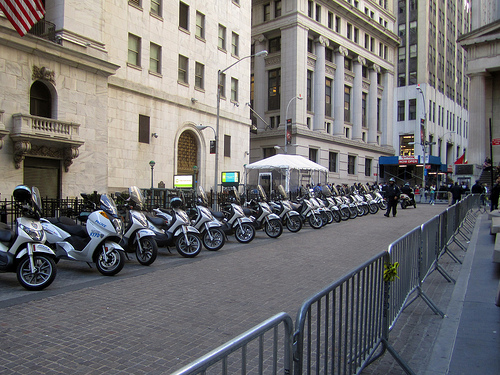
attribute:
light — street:
[203, 42, 278, 202]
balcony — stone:
[13, 110, 85, 167]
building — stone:
[394, 0, 466, 171]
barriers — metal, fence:
[117, 165, 499, 372]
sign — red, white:
[396, 152, 423, 171]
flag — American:
[1, 0, 52, 39]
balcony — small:
[12, 109, 71, 161]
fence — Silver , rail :
[164, 188, 486, 373]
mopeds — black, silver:
[3, 184, 385, 291]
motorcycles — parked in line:
[0, 174, 382, 296]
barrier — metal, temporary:
[295, 191, 486, 373]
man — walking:
[385, 175, 401, 217]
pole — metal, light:
[212, 48, 272, 198]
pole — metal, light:
[282, 91, 305, 155]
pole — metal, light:
[413, 82, 429, 202]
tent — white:
[238, 142, 332, 192]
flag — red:
[453, 148, 470, 165]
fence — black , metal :
[381, 195, 465, 342]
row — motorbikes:
[4, 183, 390, 293]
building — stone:
[5, 2, 258, 212]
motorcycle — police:
[34, 202, 127, 279]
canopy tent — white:
[242, 152, 329, 191]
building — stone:
[252, 2, 393, 179]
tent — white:
[243, 151, 327, 198]